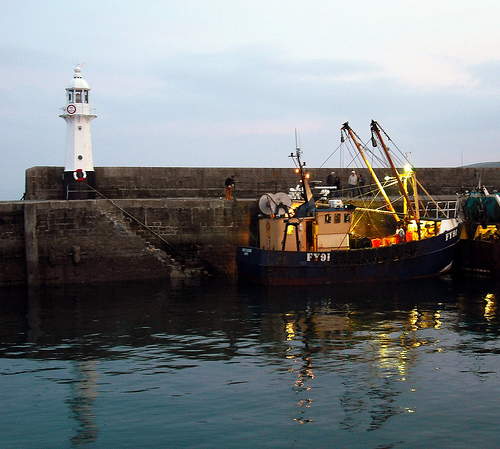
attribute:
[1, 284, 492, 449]
water — clear, blue, rippeled, disturbed, calm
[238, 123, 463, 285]
boat — dark blue, blue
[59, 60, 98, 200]
lighthouse — white, glowwing, wooden, small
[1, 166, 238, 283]
wall — grey, stone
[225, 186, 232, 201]
pants — orange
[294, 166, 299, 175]
light — orange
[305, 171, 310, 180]
light — orange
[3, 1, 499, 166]
sky — overcast, cloudy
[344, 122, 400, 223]
crane — yellow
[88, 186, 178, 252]
rail — grey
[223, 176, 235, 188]
jacket — black